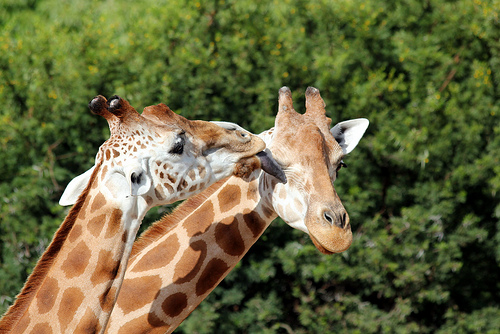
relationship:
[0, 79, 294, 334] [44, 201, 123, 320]
giraffe has coat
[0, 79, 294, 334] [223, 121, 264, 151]
giraffe has nose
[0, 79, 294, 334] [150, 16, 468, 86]
giraffe near trees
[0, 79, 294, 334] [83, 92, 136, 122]
giraffe has horns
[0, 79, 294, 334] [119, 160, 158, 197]
giraffe has ear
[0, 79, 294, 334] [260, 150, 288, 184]
giraffe has tongue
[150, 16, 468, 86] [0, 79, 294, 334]
trees behind giraffe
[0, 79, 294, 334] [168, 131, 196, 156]
giraffe has eyes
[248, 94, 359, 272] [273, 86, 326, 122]
giraffe has horns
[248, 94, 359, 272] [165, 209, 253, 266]
giraffe has neck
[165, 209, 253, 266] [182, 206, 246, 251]
neck has spots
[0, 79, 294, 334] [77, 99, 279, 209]
giraffe has head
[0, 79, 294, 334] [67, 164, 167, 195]
giraffe has ears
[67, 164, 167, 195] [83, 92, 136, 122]
ears near horns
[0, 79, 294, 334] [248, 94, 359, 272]
giraffe near giraffe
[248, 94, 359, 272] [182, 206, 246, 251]
giraffe has spots